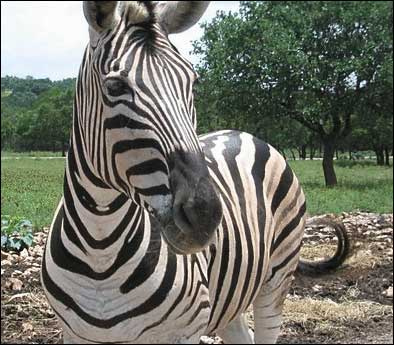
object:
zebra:
[35, 0, 359, 345]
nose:
[161, 146, 229, 241]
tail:
[300, 212, 356, 280]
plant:
[0, 216, 37, 254]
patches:
[288, 294, 393, 329]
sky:
[1, 3, 83, 73]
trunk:
[316, 107, 353, 188]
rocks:
[359, 212, 393, 244]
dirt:
[313, 208, 393, 295]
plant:
[16, 77, 76, 158]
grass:
[336, 160, 394, 209]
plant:
[257, 1, 389, 188]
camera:
[1, 2, 393, 342]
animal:
[36, 0, 317, 345]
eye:
[97, 75, 138, 103]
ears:
[77, 0, 215, 36]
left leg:
[249, 285, 289, 344]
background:
[204, 64, 388, 131]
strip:
[219, 128, 295, 225]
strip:
[214, 245, 271, 308]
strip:
[130, 27, 196, 156]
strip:
[120, 256, 190, 316]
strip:
[42, 209, 95, 284]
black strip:
[76, 57, 106, 160]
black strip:
[40, 279, 192, 337]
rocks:
[3, 252, 44, 295]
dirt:
[1, 227, 42, 338]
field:
[2, 151, 56, 217]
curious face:
[83, 27, 229, 265]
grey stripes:
[264, 155, 279, 201]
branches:
[268, 75, 323, 97]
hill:
[0, 66, 76, 114]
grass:
[360, 299, 394, 321]